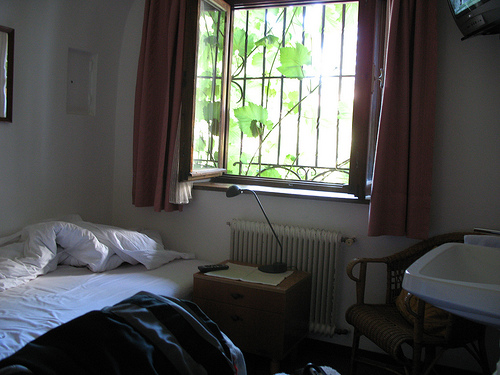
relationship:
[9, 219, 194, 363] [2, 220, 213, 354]
sheet on bed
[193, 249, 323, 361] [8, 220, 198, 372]
table next to bed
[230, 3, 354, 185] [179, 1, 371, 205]
bars are on window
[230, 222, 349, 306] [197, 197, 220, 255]
heater on wall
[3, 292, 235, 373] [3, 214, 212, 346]
blanket next to bed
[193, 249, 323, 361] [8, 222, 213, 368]
table next to bed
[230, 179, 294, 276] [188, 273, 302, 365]
object in night stand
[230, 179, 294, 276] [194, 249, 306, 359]
object in night stand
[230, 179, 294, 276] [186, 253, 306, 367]
object in stand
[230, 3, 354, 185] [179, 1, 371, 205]
bars are in window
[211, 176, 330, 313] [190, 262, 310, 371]
lamp on nightstand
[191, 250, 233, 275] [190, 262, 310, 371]
remote on nightstand